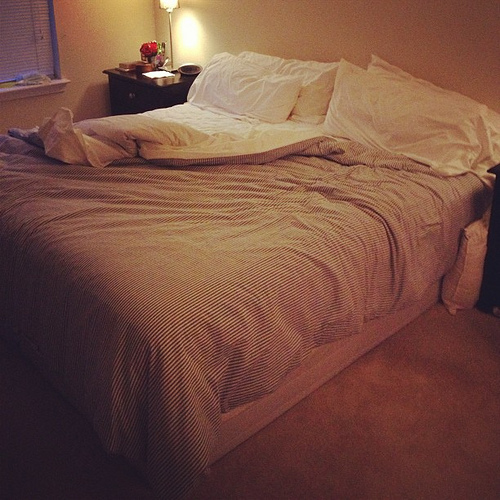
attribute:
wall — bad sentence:
[14, 321, 160, 472]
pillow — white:
[434, 206, 494, 318]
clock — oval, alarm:
[174, 56, 209, 78]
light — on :
[151, 0, 202, 62]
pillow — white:
[180, 52, 305, 130]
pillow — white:
[232, 47, 338, 129]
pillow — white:
[185, 53, 305, 125]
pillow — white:
[328, 57, 484, 174]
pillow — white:
[364, 52, 498, 165]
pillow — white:
[235, 47, 335, 123]